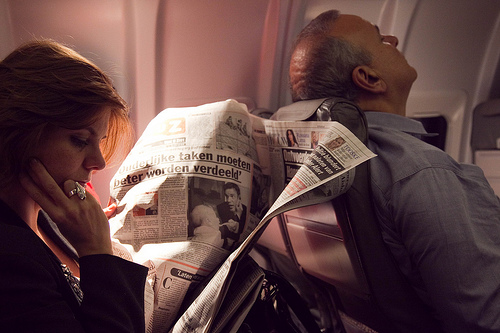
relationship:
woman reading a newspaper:
[0, 37, 150, 333] [134, 100, 354, 305]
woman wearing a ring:
[0, 37, 141, 331] [69, 181, 87, 199]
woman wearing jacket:
[0, 37, 141, 331] [7, 220, 110, 322]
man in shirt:
[284, 6, 498, 327] [366, 111, 498, 311]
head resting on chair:
[288, 5, 421, 112] [267, 92, 405, 331]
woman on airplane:
[0, 37, 141, 331] [0, 0, 496, 330]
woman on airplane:
[0, 37, 150, 333] [0, 0, 496, 330]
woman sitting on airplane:
[0, 37, 150, 333] [0, 0, 496, 330]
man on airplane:
[288, 9, 500, 333] [0, 0, 496, 330]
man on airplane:
[284, 6, 498, 327] [0, 0, 496, 330]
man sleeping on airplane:
[284, 6, 498, 327] [0, 0, 496, 330]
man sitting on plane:
[288, 9, 500, 333] [115, 16, 267, 83]